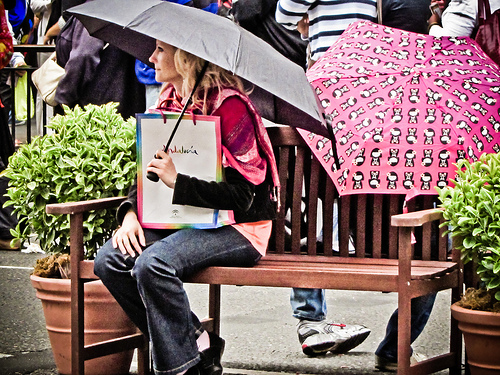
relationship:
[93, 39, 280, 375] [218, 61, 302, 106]
woman with umbrella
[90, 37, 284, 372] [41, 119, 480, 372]
woman on bench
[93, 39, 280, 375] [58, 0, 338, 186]
woman holding umbrella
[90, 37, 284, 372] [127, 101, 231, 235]
woman holding bag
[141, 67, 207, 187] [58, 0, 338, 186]
handle of umbrella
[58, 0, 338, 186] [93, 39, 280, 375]
umbrella held by woman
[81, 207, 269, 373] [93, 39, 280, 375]
pants worn by woman